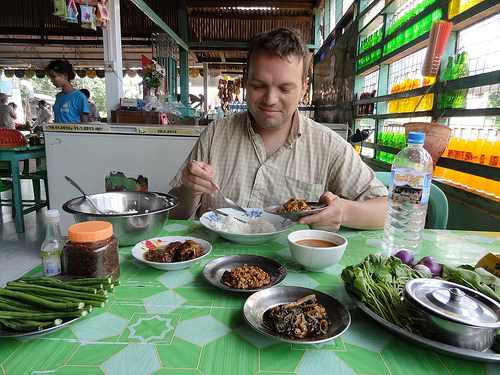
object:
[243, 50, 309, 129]
face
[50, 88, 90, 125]
shirt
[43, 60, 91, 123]
woman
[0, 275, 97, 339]
dish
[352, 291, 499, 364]
plate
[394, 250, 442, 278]
onions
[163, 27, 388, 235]
man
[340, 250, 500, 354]
food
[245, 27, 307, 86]
hair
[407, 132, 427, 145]
cap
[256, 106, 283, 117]
smiling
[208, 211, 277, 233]
white rice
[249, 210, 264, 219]
blue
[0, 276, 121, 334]
bean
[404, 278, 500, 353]
dish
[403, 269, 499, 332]
lid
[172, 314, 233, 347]
tablecloth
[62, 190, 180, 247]
bowl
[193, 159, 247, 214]
spoon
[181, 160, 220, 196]
hand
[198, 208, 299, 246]
bowl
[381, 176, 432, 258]
water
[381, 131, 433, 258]
bottle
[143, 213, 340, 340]
food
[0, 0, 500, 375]
restaurant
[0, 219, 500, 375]
dining table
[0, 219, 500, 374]
table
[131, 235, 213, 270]
dish